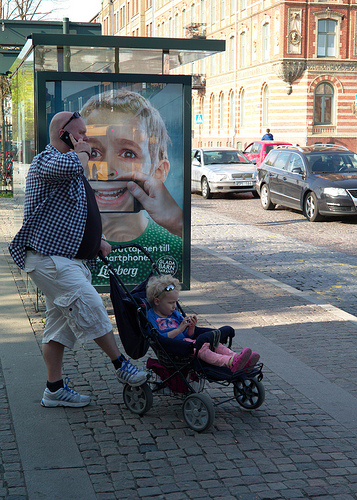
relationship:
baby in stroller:
[146, 273, 261, 381] [94, 238, 271, 435]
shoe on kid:
[234, 348, 247, 368] [144, 272, 185, 326]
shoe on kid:
[247, 351, 261, 371] [144, 272, 185, 326]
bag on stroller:
[108, 275, 153, 356] [94, 238, 271, 435]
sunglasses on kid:
[150, 280, 176, 300] [140, 271, 262, 376]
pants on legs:
[183, 335, 236, 365] [177, 328, 258, 373]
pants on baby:
[183, 335, 236, 365] [146, 273, 261, 381]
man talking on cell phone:
[22, 111, 149, 407] [59, 130, 77, 149]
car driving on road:
[255, 144, 357, 222] [195, 145, 355, 259]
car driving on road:
[200, 145, 236, 189] [195, 145, 355, 259]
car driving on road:
[258, 138, 268, 146] [195, 145, 355, 259]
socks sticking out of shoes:
[35, 354, 135, 417] [34, 348, 152, 409]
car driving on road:
[255, 144, 357, 222] [190, 192, 357, 318]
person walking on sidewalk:
[260, 129, 274, 142] [9, 169, 320, 487]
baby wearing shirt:
[146, 273, 261, 381] [153, 314, 177, 327]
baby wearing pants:
[146, 273, 261, 381] [195, 339, 233, 367]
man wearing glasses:
[22, 111, 149, 407] [62, 111, 82, 130]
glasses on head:
[62, 111, 82, 130] [46, 107, 103, 149]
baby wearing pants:
[146, 273, 261, 381] [179, 332, 256, 377]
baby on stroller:
[146, 273, 261, 381] [94, 238, 271, 435]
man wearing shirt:
[22, 111, 149, 407] [9, 147, 88, 267]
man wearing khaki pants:
[22, 111, 149, 407] [27, 259, 97, 370]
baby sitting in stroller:
[146, 273, 261, 381] [94, 238, 271, 435]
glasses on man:
[59, 110, 86, 132] [15, 103, 153, 410]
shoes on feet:
[115, 356, 152, 388] [25, 352, 154, 418]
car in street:
[257, 146, 356, 221] [186, 204, 356, 312]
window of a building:
[316, 17, 338, 60] [188, 0, 355, 156]